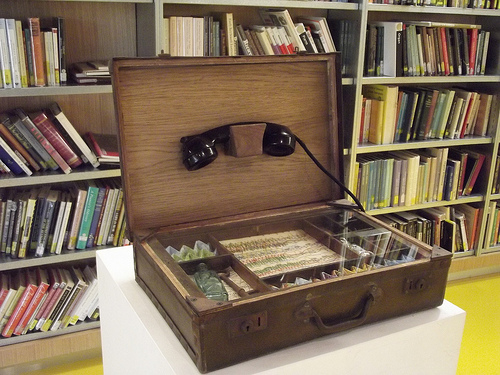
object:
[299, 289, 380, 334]
handle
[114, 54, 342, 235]
board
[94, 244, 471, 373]
stand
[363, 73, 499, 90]
shelf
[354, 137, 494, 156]
shelf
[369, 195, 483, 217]
shelf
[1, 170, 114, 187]
shelf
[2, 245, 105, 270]
shelf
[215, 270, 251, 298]
key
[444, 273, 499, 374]
floor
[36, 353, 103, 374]
floor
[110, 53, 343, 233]
lid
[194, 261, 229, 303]
bottle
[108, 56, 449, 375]
box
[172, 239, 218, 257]
white fabric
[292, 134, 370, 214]
cable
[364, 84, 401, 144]
book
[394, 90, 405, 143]
book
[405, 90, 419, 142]
book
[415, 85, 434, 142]
book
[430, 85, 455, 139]
book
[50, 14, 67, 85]
book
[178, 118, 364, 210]
telephone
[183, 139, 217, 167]
black